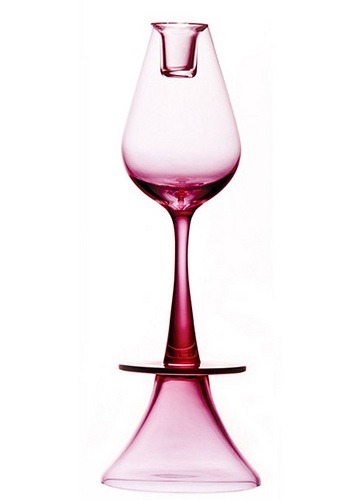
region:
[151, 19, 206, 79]
shot glass in wine goblet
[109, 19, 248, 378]
pink wine goblet on martini glass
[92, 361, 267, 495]
stemless martini glass turned upside down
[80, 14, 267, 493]
three glasses stacked atop each other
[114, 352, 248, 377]
base of wine goblet stem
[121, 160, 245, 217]
base of wine glass bowl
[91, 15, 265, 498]
three pink glasses stacked together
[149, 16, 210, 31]
top of shot glass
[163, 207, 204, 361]
stem of wine glass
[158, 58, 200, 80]
thick bottom of shot glass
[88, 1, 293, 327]
an ode shaped glass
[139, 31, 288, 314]
a drink glass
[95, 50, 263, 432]
a tall drinking glass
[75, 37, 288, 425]
a tall pink drinking glass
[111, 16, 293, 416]
a tall pink glass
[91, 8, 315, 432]
a glass that is tall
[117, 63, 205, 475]
a glass that is pink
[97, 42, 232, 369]
a glass that is tall and pink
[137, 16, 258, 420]
a tall and pink glass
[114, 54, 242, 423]
a glass for drinking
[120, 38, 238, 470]
the glass is transparent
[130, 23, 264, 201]
the glass is purple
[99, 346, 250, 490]
the glass has many shapes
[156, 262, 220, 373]
the middle is a darker purple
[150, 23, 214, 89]
the top has a cube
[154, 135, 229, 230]
there is wine in the glass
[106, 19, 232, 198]
the glass is shaped oddly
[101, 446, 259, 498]
the bottom is square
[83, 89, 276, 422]
the background is white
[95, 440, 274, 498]
the floor is white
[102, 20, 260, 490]
a cup on a stand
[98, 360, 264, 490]
a glass stand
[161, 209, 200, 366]
stem of a wine glass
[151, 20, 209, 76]
inlet on top of a glass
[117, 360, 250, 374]
base of a glass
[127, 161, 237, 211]
liquid in a glass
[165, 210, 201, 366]
red stem of a glass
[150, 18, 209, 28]
rim of a glass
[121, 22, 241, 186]
top of a glass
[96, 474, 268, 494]
rim of a stand